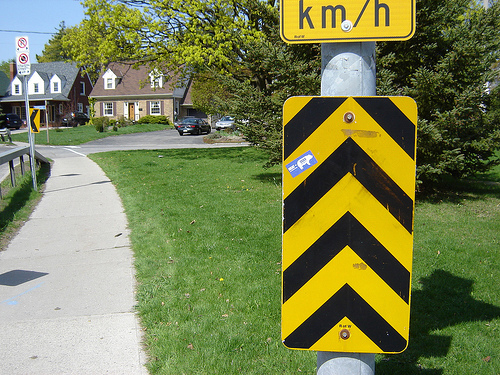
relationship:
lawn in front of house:
[6, 123, 173, 146] [89, 60, 220, 126]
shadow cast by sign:
[37, 180, 113, 193] [15, 35, 31, 51]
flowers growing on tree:
[58, 1, 278, 83] [58, 1, 279, 96]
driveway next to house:
[80, 125, 212, 145] [89, 60, 220, 126]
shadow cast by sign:
[44, 172, 80, 180] [28, 107, 42, 135]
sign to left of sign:
[15, 35, 31, 77] [281, 96, 418, 354]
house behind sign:
[89, 60, 220, 126] [281, 96, 418, 354]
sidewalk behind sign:
[1, 156, 146, 374] [28, 107, 42, 135]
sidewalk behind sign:
[1, 156, 146, 374] [15, 35, 31, 77]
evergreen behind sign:
[193, 4, 500, 193] [281, 96, 418, 354]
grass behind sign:
[87, 146, 499, 373] [281, 96, 418, 354]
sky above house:
[0, 1, 258, 65] [2, 60, 92, 129]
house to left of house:
[2, 60, 92, 129] [89, 60, 220, 126]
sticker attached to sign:
[284, 150, 318, 179] [281, 96, 418, 354]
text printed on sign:
[297, 1, 391, 29] [277, 1, 417, 45]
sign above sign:
[277, 1, 417, 45] [281, 96, 418, 354]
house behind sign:
[2, 60, 92, 129] [28, 107, 42, 135]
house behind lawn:
[89, 60, 220, 126] [6, 123, 173, 146]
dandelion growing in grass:
[219, 277, 225, 283] [87, 146, 499, 373]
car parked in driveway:
[176, 117, 212, 137] [80, 125, 212, 145]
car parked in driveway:
[215, 115, 250, 130] [80, 125, 212, 145]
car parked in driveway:
[58, 111, 89, 128] [11, 125, 73, 135]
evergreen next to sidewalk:
[193, 4, 500, 193] [1, 156, 146, 374]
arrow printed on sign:
[30, 109, 38, 132] [28, 107, 42, 135]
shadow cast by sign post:
[37, 180, 113, 193] [22, 77, 40, 193]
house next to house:
[89, 60, 220, 126] [2, 60, 92, 129]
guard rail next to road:
[2, 146, 53, 188] [2, 146, 31, 182]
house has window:
[2, 60, 92, 129] [13, 84, 20, 95]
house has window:
[2, 60, 92, 129] [34, 82, 40, 93]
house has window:
[2, 60, 92, 129] [52, 81, 59, 93]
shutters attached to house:
[145, 100, 166, 117] [89, 60, 220, 126]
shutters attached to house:
[98, 101, 118, 119] [89, 60, 220, 126]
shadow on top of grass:
[379, 271, 500, 374] [87, 146, 499, 373]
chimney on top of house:
[9, 60, 17, 80] [2, 60, 92, 129]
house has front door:
[89, 60, 220, 126] [127, 102, 136, 120]